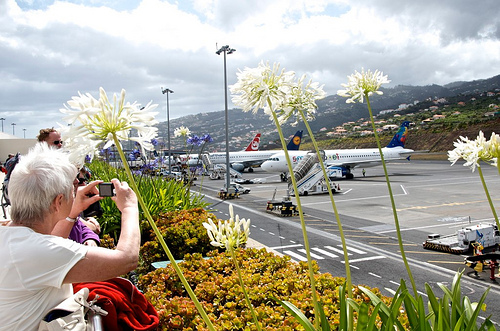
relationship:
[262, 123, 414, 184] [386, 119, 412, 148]
airplane with tail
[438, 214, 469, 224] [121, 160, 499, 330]
paint on asphalt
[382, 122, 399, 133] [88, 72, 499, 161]
houses on hill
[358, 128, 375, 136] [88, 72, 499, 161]
houses on hill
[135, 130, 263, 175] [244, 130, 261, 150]
airplane with tail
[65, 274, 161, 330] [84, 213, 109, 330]
jacket over wall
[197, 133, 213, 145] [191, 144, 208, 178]
flower with stems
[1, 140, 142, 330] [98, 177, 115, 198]
person taking picture with cellphone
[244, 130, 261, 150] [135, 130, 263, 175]
tail of airplane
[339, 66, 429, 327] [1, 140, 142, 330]
flowers in front of person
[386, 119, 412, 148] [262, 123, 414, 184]
tail on airplane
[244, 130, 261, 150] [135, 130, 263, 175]
tail on airplane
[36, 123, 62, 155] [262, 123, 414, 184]
people watching airplane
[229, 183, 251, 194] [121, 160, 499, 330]
car on asphalt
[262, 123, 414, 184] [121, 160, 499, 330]
airplane on asphalt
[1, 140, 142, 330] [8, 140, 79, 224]
person with hair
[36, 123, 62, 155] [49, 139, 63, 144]
people wearing sunglasses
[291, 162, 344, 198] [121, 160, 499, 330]
truck on asphalt